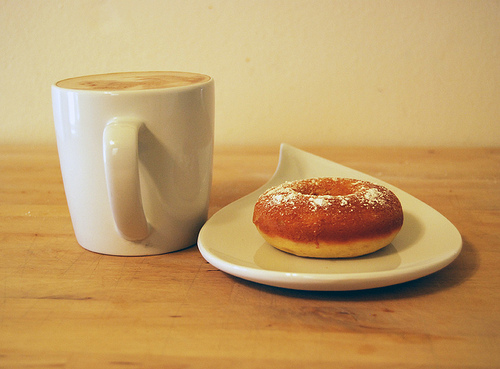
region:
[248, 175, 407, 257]
Doughnut with sugar on top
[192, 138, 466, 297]
Tear drop shaped plate on table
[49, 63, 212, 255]
White mug full of liquid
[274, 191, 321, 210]
Sugar sprinkled on top a doughnut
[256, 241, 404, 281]
Shadow on plate of a doughnut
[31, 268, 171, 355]
Wooden surface with light scratches in it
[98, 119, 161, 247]
white handle of coffee cup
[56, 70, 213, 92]
Brown and tan liquid in white coffee cup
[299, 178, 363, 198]
hole in the middle of doughnut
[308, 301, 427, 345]
spots on the brown table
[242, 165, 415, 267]
Donut over a dish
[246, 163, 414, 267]
Donut is dusted with powdered sugar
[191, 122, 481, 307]
Dish is white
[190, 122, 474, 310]
Dish has a dandle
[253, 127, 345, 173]
Handle of a dish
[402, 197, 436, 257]
Shadow of donut on the dish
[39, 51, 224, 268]
Cup is white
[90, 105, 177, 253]
Handle of cup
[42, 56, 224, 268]
Cup has a drink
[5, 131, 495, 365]
Table is brown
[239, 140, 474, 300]
Donut on white plate.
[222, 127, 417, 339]
white plate under donut.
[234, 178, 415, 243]
Powdered sugar on donut.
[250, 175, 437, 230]
White colored powdered sugar.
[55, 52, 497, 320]
Cup and plate on table.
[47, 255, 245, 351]
Wooden table with plates on it.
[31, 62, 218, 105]
coffee in a cup.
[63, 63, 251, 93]
Coffee with cream in it.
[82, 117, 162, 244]
White handle of mug.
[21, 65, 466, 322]
Two ceramic items on table.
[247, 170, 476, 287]
Donut on the white plate.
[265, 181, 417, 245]
Powdered sugar on the donut,.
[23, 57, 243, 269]
Cup on the table.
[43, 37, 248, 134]
Coffee in the mug.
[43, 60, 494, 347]
Plates and mug on the table.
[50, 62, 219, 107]
White foam on coffee.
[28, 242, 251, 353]
Wooden style of table.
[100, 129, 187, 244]
Handle on the cup.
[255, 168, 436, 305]
Beige and white donut.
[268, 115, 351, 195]
Point on the white plate.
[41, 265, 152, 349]
the table is wooden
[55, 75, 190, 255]
this is a cup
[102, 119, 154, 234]
this is a cup handle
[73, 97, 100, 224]
the cup is white in color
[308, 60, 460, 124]
the wall is white in color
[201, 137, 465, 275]
this is a saucer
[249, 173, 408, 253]
this is a doughnut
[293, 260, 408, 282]
the saucer is white in lion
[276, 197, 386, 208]
the doughnut has some sprinkles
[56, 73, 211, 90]
the cup is full